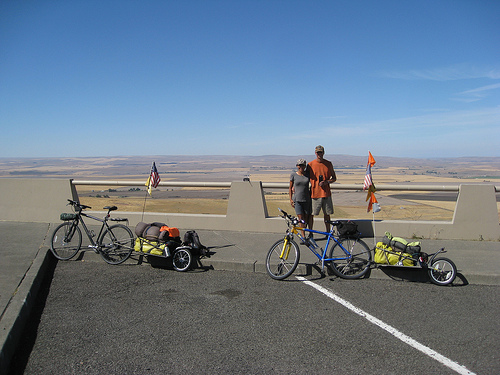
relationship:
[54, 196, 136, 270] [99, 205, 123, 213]
bicycle with seat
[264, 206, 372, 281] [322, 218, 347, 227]
bicycle with seat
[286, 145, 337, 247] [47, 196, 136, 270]
owners of bicycle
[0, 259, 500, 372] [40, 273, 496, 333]
parking lot with segments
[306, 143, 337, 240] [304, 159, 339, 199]
male with shirt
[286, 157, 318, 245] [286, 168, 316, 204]
female with shirt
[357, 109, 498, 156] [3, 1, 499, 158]
clouds in sky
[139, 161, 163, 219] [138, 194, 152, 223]
flag from stick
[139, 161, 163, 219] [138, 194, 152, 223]
flag hanging on stick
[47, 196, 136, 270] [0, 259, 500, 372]
bicycle in lot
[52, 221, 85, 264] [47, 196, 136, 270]
tire on bicycle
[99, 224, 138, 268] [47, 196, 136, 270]
tire on bicycle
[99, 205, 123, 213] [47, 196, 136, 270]
seat on bicycle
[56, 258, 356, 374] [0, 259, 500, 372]
pavement on ground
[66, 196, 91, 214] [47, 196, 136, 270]
handle bars on bicycle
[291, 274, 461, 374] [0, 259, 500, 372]
line in road